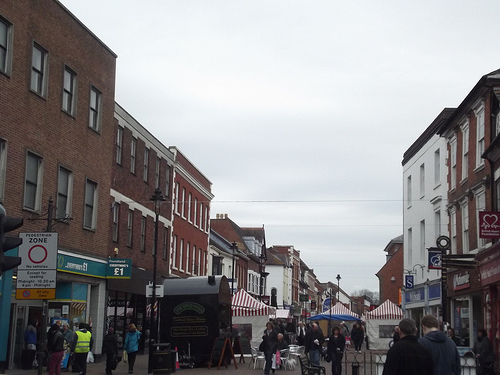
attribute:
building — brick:
[2, 0, 119, 372]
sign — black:
[165, 298, 213, 341]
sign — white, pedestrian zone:
[18, 231, 57, 288]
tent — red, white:
[229, 284, 276, 320]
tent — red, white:
[366, 299, 404, 321]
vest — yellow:
[74, 329, 93, 357]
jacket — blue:
[126, 331, 138, 356]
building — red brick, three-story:
[170, 142, 214, 284]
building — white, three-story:
[397, 107, 446, 336]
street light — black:
[145, 185, 169, 373]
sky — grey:
[62, 1, 499, 292]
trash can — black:
[145, 339, 174, 374]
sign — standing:
[207, 334, 241, 374]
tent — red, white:
[308, 300, 361, 345]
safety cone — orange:
[174, 347, 183, 370]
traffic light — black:
[1, 211, 28, 277]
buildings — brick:
[0, 1, 323, 368]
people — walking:
[22, 306, 141, 373]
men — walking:
[380, 316, 464, 374]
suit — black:
[330, 334, 345, 374]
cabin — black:
[160, 271, 240, 369]